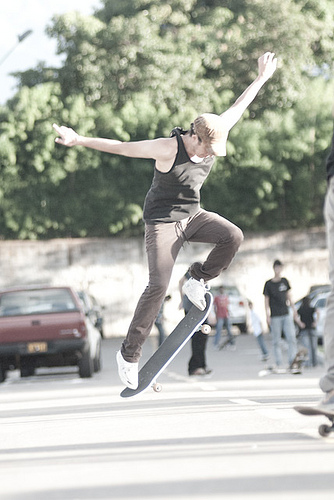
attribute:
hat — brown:
[186, 116, 231, 150]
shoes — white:
[117, 275, 204, 392]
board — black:
[117, 293, 233, 394]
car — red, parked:
[2, 288, 92, 362]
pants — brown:
[121, 227, 235, 317]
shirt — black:
[145, 147, 198, 224]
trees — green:
[51, 18, 256, 84]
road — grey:
[27, 399, 219, 490]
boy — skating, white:
[39, 89, 266, 338]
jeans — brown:
[126, 223, 244, 285]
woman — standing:
[295, 303, 333, 347]